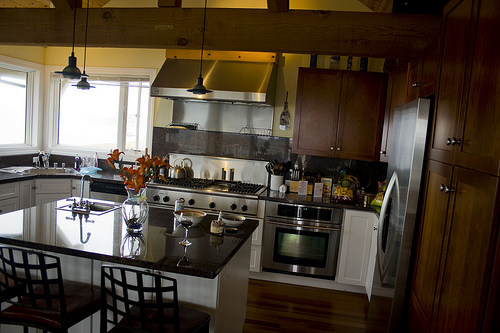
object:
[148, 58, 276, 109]
vent hood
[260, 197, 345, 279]
oven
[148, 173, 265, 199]
stove top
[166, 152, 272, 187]
backsplash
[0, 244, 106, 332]
chair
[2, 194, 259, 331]
island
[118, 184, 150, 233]
vase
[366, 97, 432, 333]
refrigerator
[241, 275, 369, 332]
floor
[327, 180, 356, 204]
food items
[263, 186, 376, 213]
counter top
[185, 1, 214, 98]
light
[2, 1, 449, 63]
ceiling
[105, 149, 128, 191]
flowers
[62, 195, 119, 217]
sink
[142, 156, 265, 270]
stove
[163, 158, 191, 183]
teapot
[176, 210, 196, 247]
wine glass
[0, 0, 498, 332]
kitchen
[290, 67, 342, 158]
cupboards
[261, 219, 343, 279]
door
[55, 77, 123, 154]
windows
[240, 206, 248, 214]
knobs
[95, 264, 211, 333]
chair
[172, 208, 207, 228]
bowls